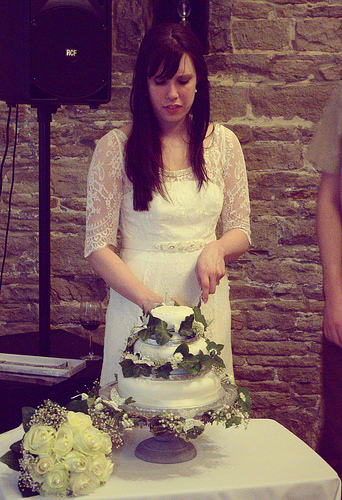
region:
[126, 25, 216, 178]
The woman's hair is down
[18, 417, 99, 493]
The roses are white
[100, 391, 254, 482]
The cake is on a stand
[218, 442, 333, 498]
The table cloth is white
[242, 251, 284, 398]
The wall is brick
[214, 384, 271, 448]
The leaves are green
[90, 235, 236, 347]
The woman is cutting the cake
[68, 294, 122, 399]
The glass has a drink in it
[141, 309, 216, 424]
The cake is 3 teirs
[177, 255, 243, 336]
The woman has a knife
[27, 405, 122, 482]
WHITE ROSES ON THE BOQUET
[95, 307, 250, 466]
THREE TIERED WEDDING CAKE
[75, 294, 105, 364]
GLASS OF WINE TO THE LEFT OF BRIDE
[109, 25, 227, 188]
BRIDE HAS AUBURN HAIR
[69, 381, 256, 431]
FLOWERS AROUND THE BOTTOM OF CAKE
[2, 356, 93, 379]
GIFT BOX ON THE TABLE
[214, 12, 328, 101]
STONE WALL IN BACKGROUND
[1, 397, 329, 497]
CAKE IS ON A TABLE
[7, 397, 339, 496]
TABLE HAS WHITE TABLE CLOTH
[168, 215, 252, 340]
KNIFE IS IN HER LEFT HAND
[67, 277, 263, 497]
a cake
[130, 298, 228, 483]
a cake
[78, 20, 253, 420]
woman is cutting a cake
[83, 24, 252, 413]
woman is wearing bridal gown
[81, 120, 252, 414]
bridal gown is white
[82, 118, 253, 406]
bridal gown has lace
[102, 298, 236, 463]
cake is on a stand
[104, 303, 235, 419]
cake has three layers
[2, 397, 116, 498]
boquet of flowers on table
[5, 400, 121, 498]
boquet has white roses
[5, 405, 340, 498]
table with white tablecloth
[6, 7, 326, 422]
brick wall in the background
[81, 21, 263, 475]
bride cutting wedding cake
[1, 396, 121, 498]
bouquet of roses on the table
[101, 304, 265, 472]
wedding cake on the table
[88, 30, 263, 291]
woman in a white wedding dress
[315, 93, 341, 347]
arm of person to the right of the bride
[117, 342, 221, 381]
green leaves decorating the cake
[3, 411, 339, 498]
white tablecloth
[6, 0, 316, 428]
stone wall behind the bride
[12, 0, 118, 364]
tall black speaker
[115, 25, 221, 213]
woman with long, straight brown hair